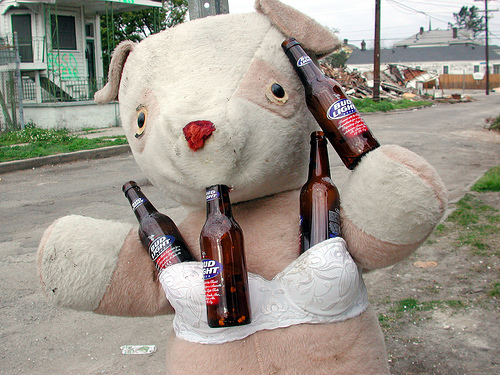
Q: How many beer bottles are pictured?
A: Four.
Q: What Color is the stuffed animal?
A: Tan and beige.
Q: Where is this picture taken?
A: Street.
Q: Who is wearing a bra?
A: The stuffed animal.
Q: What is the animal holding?
A: Beer.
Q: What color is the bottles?
A: Brown.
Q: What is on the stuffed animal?
A: Strapless bra.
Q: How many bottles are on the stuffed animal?
A: Four.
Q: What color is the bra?
A: White.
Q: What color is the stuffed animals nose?
A: Red.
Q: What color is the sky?
A: Blue.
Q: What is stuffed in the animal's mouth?
A: Beer bottle.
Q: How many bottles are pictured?
A: Four.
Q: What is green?
A: Grass.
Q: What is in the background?
A: A house.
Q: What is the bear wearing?
A: A bra.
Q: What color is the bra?
A: White.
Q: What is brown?
A: Bottles.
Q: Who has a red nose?
A: Teddy bear.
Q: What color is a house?
A: White.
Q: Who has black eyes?
A: The teddy bear.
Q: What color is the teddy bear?
A: Beige.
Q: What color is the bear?
A: Pink.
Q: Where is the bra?
A: On the bear.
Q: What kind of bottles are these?
A: Beer.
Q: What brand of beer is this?
A: Bud light.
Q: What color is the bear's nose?
A: Red.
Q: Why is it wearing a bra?
A: A prank.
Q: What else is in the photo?
A: Beer bottles.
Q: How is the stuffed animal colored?
A: Pink and white.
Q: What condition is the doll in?
A: Bad.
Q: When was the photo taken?
A: Daytime.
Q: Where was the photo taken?
A: On the street.